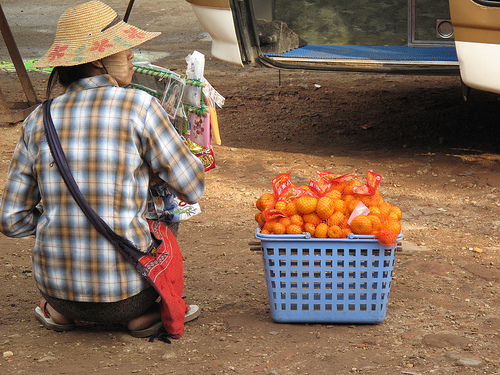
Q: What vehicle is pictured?
A: The vehicle is a van.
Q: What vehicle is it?
A: The vehicle is a van.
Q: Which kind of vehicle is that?
A: This is a van.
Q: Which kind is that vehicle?
A: This is a van.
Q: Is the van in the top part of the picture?
A: Yes, the van is in the top of the image.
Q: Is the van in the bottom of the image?
A: No, the van is in the top of the image.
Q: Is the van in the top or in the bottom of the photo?
A: The van is in the top of the image.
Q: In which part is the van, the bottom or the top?
A: The van is in the top of the image.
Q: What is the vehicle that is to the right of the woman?
A: The vehicle is a van.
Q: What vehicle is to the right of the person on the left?
A: The vehicle is a van.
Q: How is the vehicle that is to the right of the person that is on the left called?
A: The vehicle is a van.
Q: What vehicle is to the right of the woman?
A: The vehicle is a van.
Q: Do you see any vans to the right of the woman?
A: Yes, there is a van to the right of the woman.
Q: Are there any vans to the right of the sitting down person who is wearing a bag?
A: Yes, there is a van to the right of the woman.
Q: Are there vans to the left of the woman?
A: No, the van is to the right of the woman.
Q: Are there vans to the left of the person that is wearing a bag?
A: No, the van is to the right of the woman.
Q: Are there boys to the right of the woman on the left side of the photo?
A: No, there is a van to the right of the woman.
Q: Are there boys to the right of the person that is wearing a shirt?
A: No, there is a van to the right of the woman.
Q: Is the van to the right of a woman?
A: Yes, the van is to the right of a woman.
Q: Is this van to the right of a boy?
A: No, the van is to the right of a woman.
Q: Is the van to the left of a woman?
A: No, the van is to the right of a woman.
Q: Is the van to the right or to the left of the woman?
A: The van is to the right of the woman.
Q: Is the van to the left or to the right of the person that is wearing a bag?
A: The van is to the right of the woman.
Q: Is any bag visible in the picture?
A: Yes, there is a bag.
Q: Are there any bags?
A: Yes, there is a bag.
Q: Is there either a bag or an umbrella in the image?
A: Yes, there is a bag.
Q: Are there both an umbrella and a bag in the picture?
A: No, there is a bag but no umbrellas.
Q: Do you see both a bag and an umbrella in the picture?
A: No, there is a bag but no umbrellas.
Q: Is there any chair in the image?
A: No, there are no chairs.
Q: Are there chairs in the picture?
A: No, there are no chairs.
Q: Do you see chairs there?
A: No, there are no chairs.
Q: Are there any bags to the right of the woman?
A: Yes, there is a bag to the right of the woman.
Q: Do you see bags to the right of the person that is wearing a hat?
A: Yes, there is a bag to the right of the woman.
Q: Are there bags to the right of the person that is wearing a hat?
A: Yes, there is a bag to the right of the woman.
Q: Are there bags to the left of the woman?
A: No, the bag is to the right of the woman.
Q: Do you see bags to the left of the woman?
A: No, the bag is to the right of the woman.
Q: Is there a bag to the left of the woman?
A: No, the bag is to the right of the woman.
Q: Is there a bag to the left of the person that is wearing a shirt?
A: No, the bag is to the right of the woman.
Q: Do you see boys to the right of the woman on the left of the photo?
A: No, there is a bag to the right of the woman.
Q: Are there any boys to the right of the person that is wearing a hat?
A: No, there is a bag to the right of the woman.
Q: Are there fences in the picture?
A: No, there are no fences.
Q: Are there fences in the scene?
A: No, there are no fences.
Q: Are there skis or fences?
A: No, there are no fences or skis.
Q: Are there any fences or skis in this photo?
A: No, there are no fences or skis.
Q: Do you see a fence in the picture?
A: No, there are no fences.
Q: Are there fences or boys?
A: No, there are no fences or boys.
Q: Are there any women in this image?
A: Yes, there is a woman.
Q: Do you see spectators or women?
A: Yes, there is a woman.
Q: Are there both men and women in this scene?
A: No, there is a woman but no men.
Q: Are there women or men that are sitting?
A: Yes, the woman is sitting.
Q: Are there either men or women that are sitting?
A: Yes, the woman is sitting.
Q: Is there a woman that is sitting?
A: Yes, there is a woman that is sitting.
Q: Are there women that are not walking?
A: Yes, there is a woman that is sitting.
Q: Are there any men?
A: No, there are no men.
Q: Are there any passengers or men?
A: No, there are no men or passengers.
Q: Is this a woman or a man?
A: This is a woman.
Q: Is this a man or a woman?
A: This is a woman.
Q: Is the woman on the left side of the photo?
A: Yes, the woman is on the left of the image.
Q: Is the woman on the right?
A: No, the woman is on the left of the image.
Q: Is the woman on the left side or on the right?
A: The woman is on the left of the image.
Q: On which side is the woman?
A: The woman is on the left of the image.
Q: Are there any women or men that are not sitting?
A: No, there is a woman but she is sitting.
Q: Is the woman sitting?
A: Yes, the woman is sitting.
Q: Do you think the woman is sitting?
A: Yes, the woman is sitting.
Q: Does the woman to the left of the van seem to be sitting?
A: Yes, the woman is sitting.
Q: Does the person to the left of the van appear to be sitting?
A: Yes, the woman is sitting.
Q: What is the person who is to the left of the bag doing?
A: The woman is sitting.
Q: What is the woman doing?
A: The woman is sitting.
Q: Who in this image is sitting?
A: The woman is sitting.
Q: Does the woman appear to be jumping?
A: No, the woman is sitting.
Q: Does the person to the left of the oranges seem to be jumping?
A: No, the woman is sitting.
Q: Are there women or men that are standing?
A: No, there is a woman but she is sitting.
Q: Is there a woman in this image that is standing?
A: No, there is a woman but she is sitting.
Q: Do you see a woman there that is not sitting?
A: No, there is a woman but she is sitting.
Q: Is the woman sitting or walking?
A: The woman is sitting.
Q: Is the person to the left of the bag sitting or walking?
A: The woman is sitting.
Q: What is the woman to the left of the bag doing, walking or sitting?
A: The woman is sitting.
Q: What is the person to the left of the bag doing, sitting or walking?
A: The woman is sitting.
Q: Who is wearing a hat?
A: The woman is wearing a hat.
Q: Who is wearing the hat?
A: The woman is wearing a hat.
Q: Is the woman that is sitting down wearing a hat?
A: Yes, the woman is wearing a hat.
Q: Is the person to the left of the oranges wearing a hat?
A: Yes, the woman is wearing a hat.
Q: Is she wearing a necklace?
A: No, the woman is wearing a hat.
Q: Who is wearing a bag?
A: The woman is wearing a bag.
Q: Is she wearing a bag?
A: Yes, the woman is wearing a bag.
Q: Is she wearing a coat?
A: No, the woman is wearing a bag.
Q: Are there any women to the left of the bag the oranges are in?
A: Yes, there is a woman to the left of the bag.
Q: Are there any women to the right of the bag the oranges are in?
A: No, the woman is to the left of the bag.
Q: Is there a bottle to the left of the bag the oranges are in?
A: No, there is a woman to the left of the bag.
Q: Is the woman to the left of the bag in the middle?
A: Yes, the woman is to the left of the bag.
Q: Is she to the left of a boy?
A: No, the woman is to the left of the bag.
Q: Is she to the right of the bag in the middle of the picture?
A: No, the woman is to the left of the bag.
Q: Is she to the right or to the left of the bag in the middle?
A: The woman is to the left of the bag.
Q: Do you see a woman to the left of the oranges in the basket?
A: Yes, there is a woman to the left of the oranges.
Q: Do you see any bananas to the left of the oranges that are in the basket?
A: No, there is a woman to the left of the oranges.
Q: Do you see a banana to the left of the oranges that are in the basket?
A: No, there is a woman to the left of the oranges.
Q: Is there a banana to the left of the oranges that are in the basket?
A: No, there is a woman to the left of the oranges.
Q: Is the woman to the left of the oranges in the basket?
A: Yes, the woman is to the left of the oranges.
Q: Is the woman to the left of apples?
A: No, the woman is to the left of the oranges.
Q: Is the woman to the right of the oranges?
A: No, the woman is to the left of the oranges.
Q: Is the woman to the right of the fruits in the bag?
A: No, the woman is to the left of the oranges.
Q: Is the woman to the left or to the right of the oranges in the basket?
A: The woman is to the left of the oranges.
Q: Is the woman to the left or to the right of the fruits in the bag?
A: The woman is to the left of the oranges.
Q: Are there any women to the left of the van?
A: Yes, there is a woman to the left of the van.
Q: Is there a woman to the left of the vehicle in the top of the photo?
A: Yes, there is a woman to the left of the van.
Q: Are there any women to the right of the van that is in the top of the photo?
A: No, the woman is to the left of the van.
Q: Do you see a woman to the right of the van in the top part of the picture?
A: No, the woman is to the left of the van.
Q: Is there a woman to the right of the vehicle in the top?
A: No, the woman is to the left of the van.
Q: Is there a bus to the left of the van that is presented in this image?
A: No, there is a woman to the left of the van.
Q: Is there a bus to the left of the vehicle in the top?
A: No, there is a woman to the left of the van.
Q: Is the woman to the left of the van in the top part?
A: Yes, the woman is to the left of the van.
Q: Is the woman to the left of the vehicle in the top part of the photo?
A: Yes, the woman is to the left of the van.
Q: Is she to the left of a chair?
A: No, the woman is to the left of the van.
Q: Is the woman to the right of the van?
A: No, the woman is to the left of the van.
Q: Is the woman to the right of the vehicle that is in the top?
A: No, the woman is to the left of the van.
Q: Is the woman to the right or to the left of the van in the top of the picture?
A: The woman is to the left of the van.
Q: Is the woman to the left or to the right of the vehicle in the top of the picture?
A: The woman is to the left of the van.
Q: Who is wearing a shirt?
A: The woman is wearing a shirt.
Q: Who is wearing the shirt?
A: The woman is wearing a shirt.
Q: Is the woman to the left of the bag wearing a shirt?
A: Yes, the woman is wearing a shirt.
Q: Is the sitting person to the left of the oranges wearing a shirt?
A: Yes, the woman is wearing a shirt.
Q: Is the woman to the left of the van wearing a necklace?
A: No, the woman is wearing a shirt.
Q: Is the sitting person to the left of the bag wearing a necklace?
A: No, the woman is wearing a shirt.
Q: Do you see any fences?
A: No, there are no fences.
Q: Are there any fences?
A: No, there are no fences.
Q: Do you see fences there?
A: No, there are no fences.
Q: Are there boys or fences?
A: No, there are no fences or boys.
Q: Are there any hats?
A: Yes, there is a hat.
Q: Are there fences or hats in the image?
A: Yes, there is a hat.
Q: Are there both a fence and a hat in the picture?
A: No, there is a hat but no fences.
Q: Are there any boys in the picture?
A: No, there are no boys.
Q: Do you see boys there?
A: No, there are no boys.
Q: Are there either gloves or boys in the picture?
A: No, there are no boys or gloves.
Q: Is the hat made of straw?
A: Yes, the hat is made of straw.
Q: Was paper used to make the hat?
A: No, the hat is made of straw.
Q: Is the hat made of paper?
A: No, the hat is made of straw.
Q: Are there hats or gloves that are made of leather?
A: No, there is a hat but it is made of straw.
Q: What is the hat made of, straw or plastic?
A: The hat is made of straw.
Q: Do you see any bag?
A: Yes, there is a bag.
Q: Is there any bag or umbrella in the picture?
A: Yes, there is a bag.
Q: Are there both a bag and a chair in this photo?
A: No, there is a bag but no chairs.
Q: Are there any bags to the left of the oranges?
A: Yes, there is a bag to the left of the oranges.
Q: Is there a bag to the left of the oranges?
A: Yes, there is a bag to the left of the oranges.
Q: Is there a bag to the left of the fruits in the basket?
A: Yes, there is a bag to the left of the oranges.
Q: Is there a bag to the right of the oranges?
A: No, the bag is to the left of the oranges.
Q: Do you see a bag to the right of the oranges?
A: No, the bag is to the left of the oranges.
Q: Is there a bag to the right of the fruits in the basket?
A: No, the bag is to the left of the oranges.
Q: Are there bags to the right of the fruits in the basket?
A: No, the bag is to the left of the oranges.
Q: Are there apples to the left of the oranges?
A: No, there is a bag to the left of the oranges.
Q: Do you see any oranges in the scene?
A: Yes, there are oranges.